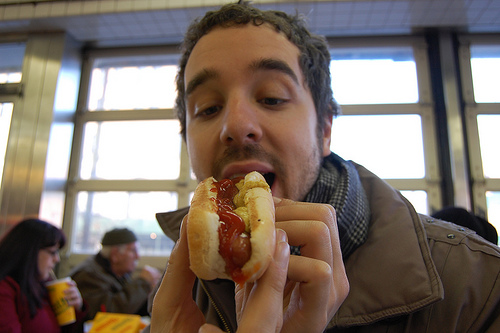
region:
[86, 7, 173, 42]
A white checked roof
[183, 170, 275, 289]
A tasty looking burger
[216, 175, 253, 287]
A slimy red jelly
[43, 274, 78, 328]
A yellow plastic cup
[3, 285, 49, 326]
A fitting maroon top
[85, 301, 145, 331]
A bright yellow box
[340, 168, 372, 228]
A dark checked shirt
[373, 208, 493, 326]
A brown stylish jacket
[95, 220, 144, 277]
An old white man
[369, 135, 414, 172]
A clear white sky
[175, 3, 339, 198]
A man with brown hair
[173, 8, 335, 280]
A man eating a hot dog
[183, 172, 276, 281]
a hot dog with ketsup and mustard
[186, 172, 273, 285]
A hot dog in a bun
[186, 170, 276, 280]
A hot dog with condiments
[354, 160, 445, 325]
A brown coat collar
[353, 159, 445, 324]
The brown collar of a man's jacket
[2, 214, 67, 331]
A woman with dark brown hair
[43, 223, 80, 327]
A woman drinking from a yellow cup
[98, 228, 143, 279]
A man wearing a skull cap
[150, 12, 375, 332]
guy ready to bite into hotdog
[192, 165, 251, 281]
catsup spread on hotdog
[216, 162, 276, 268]
mustard spread over hotdog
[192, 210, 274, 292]
catsup dripping off hotdog bun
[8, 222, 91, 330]
female drinking from disposable cup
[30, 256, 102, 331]
green and yellow cup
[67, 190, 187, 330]
man wearing dark hat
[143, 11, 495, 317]
guy wearing brown jacket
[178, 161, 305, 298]
hotdog and bun with catsup and mustard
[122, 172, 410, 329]
hands holding hotdog in bun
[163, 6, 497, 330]
man eating a hotdog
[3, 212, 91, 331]
woman drinking from yellow cup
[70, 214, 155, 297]
man with gray hair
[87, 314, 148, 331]
yellow box in front of woman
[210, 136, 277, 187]
mustache of man eating hotdog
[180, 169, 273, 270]
hotdog in hotdog bun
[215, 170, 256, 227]
mustard and ketchup on hotdog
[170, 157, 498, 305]
coat of man eating hotdog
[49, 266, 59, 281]
white straw in yellow cup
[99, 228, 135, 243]
cap of man with gray hair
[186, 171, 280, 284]
A hot dog with ketchup on it.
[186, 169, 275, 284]
A bun with a hot dog between it.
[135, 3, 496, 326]
A person holding a hot dog.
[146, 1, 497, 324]
A man eating a hot dog.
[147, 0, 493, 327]
A man who has started eating a hot dog.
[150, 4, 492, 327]
A man wearing a brown jacket eating a hot dog.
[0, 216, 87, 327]
A woman with black hair behind the man eating hot dog.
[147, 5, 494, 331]
A man with short black hair eating.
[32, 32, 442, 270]
A large window in the background.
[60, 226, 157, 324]
An old man sitting next to a woman.